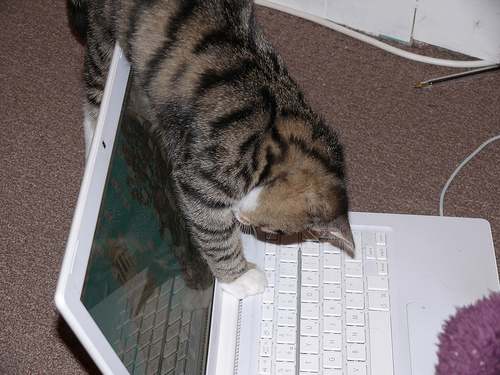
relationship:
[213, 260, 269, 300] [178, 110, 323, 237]
paw on cat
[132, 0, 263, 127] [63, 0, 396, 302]
stripes on cat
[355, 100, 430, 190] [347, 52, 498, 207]
carpet on floor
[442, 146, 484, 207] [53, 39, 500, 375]
white cord attached to computer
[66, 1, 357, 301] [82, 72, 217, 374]
cat looking at computer screen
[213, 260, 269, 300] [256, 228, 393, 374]
paw on keyboard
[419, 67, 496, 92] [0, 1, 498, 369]
pen laying on floor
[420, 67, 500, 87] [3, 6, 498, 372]
pen laying on carpet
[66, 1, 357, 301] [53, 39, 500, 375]
cat touching a computer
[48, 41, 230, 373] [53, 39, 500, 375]
lid of a computer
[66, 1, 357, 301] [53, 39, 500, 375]
cat playing on computer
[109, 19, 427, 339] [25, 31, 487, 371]
cat on computer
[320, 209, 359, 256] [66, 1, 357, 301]
ear of a cat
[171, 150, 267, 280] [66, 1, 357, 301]
cat leg on cat